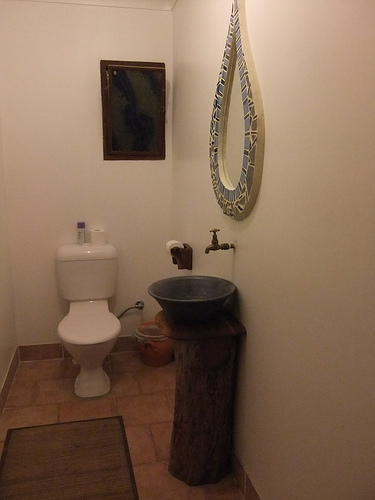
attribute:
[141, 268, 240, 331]
sink — elevated, gray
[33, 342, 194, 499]
floor — orange, tiled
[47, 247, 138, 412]
toilet — white, clean